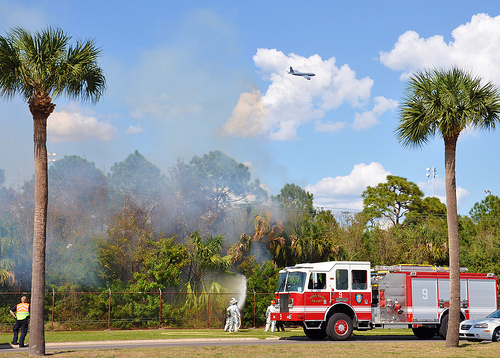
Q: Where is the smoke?
A: In the forest.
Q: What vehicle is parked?
A: A fire truck.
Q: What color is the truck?
A: Red.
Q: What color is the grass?
A: Green.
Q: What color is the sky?
A: Blue.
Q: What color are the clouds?
A: White.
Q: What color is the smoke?
A: Gray.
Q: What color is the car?
A: White.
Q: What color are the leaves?
A: Green.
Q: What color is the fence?
A: Gray.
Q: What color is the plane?
A: Gray.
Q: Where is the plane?
A: In the sky.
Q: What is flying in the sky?
A: Airplane.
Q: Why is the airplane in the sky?
A: Flying.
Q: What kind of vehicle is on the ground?
A: Fire engine.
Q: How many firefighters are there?
A: 3.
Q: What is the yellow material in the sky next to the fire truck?
A: Smoke.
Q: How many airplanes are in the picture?
A: One.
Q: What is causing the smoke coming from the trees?
A: A fire.